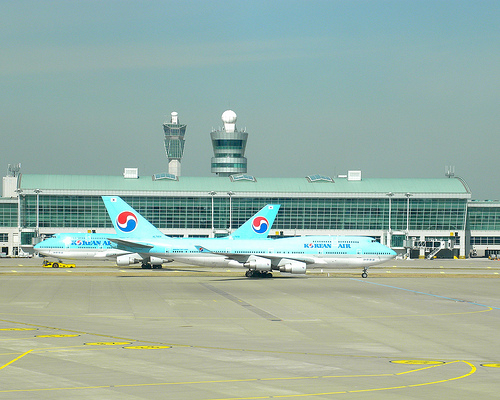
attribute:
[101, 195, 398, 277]
airplane — korean air, light blue, blue, white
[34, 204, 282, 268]
airplane — korean air, light blue, blue, white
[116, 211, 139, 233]
logo — blue white, circle, red, round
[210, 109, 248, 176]
control tower — windowed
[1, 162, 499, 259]
terminal — blue, white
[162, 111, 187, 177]
control tower — windowed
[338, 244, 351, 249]
word air — blue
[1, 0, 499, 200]
sky — clear, blue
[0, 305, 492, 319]
line — yellow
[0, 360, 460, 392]
line — yellow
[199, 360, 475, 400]
line — yellow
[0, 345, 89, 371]
line — yellow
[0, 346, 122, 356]
line — yellow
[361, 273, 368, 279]
tire — round, black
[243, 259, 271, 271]
engine — white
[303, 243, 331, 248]
word korean — blue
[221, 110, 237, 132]
object — white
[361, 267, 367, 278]
landing gear — out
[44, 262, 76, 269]
object — yellow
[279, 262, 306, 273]
engine — white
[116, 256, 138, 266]
engine — white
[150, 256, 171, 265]
engine — white